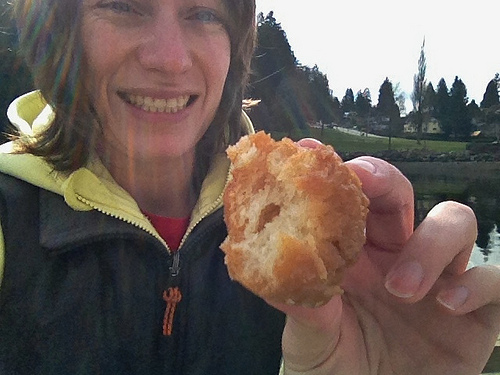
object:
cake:
[218, 130, 379, 311]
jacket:
[0, 178, 280, 374]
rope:
[160, 286, 181, 337]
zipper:
[168, 249, 181, 288]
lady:
[1, 0, 498, 375]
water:
[416, 155, 498, 266]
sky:
[253, 0, 499, 107]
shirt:
[150, 216, 186, 248]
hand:
[275, 136, 500, 375]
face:
[76, 0, 232, 162]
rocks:
[482, 151, 490, 158]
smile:
[113, 86, 205, 124]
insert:
[0, 89, 253, 253]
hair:
[10, 0, 260, 176]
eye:
[91, 0, 145, 17]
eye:
[175, 0, 223, 23]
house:
[400, 107, 446, 134]